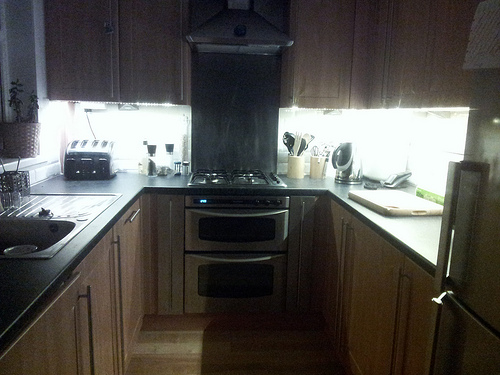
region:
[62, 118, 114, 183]
there is a four slice toaster on the counter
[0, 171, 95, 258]
the sink is on this side of the kitchen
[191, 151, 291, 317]
the oven range is in the middle of the kitchen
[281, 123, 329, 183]
there are some kitchen utensils on the counter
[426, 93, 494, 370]
this is a portion of the refrigerator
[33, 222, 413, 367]
the cupboards are made up of wood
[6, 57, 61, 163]
there is a plant in the kitchen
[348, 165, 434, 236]
a cutting board is on the counter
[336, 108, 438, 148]
there is a very bright light on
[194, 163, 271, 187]
these are the burners for the stove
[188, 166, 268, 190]
top of gas cooking stove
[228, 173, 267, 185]
front right burner on stove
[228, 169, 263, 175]
back right burner on stove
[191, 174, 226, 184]
front left burner on stove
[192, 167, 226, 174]
back left burner on stove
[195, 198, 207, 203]
blue light on stove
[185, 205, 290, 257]
top oven on stove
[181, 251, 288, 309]
bottom oven on stove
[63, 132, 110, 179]
four slice toaster on cabinet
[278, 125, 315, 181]
cooking utensils in a vase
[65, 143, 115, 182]
black toaster on the counter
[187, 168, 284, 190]
range top above the oven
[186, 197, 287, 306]
stainless steel oven in the kitchen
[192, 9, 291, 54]
stainless steel range hood above the stove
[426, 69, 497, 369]
stainless steel refrigerator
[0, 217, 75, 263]
kitchen sink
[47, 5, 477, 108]
upper kitchen cabinets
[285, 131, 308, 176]
wooden holder on counter full of spoons and spatulas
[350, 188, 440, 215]
a wood cutting board on the counter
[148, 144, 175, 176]
salt and pepper grinders to the left of the stove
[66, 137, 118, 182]
Toaster on the counter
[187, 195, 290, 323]
Two ovens in the kitchen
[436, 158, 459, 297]
Silver handle of the freezer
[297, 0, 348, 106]
Wooden cabinets in the kitchen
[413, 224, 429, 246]
Small part of black counter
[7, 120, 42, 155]
Basket that has plants in it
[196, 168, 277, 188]
Black stove in kitchen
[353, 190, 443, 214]
Tan cutting board on counter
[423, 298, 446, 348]
Top of silver handle on refrigerator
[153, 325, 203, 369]
Wooden floor in kitchen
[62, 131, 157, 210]
a toaster on the counter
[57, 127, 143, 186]
a toaster on the counter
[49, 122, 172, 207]
a toaster on the counter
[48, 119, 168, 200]
a toaster on the counter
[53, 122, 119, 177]
a toaster on the counter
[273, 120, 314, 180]
the cabinets are closed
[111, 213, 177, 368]
the cabinets are closed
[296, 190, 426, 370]
the cabinets are closed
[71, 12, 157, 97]
the cabinets are closed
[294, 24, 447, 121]
the cabinets are closed